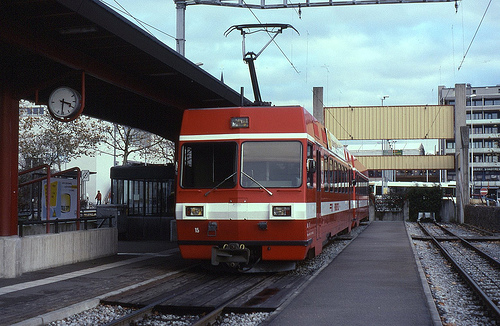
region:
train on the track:
[153, 94, 393, 275]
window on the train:
[181, 147, 299, 184]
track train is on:
[152, 265, 270, 307]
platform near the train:
[40, 257, 165, 272]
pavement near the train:
[347, 245, 422, 302]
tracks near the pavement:
[412, 226, 499, 268]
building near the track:
[441, 66, 499, 198]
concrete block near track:
[18, 225, 126, 261]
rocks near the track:
[443, 287, 468, 311]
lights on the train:
[181, 197, 298, 219]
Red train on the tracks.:
[172, 97, 383, 266]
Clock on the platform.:
[42, 83, 85, 122]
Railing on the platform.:
[97, 153, 182, 253]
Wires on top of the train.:
[232, 7, 376, 112]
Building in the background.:
[435, 76, 498, 226]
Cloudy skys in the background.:
[121, 2, 498, 122]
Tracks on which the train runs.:
[72, 210, 497, 322]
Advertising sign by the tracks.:
[17, 163, 91, 230]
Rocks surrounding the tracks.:
[25, 216, 499, 321]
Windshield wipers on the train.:
[200, 167, 275, 194]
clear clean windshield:
[182, 140, 302, 194]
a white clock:
[50, 83, 85, 117]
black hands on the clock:
[57, 95, 72, 111]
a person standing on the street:
[95, 189, 105, 201]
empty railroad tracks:
[407, 217, 498, 322]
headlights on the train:
[181, 200, 299, 220]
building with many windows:
[437, 88, 498, 199]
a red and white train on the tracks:
[172, 108, 396, 266]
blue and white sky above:
[115, 4, 492, 99]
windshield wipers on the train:
[200, 174, 272, 196]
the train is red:
[184, 108, 419, 270]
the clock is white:
[27, 80, 100, 127]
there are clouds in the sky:
[215, 20, 472, 123]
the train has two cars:
[184, 130, 386, 245]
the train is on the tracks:
[162, 124, 362, 308]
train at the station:
[7, 117, 409, 312]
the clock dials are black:
[42, 76, 74, 113]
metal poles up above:
[224, 8, 304, 61]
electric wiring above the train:
[216, 13, 487, 175]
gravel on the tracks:
[433, 222, 477, 314]